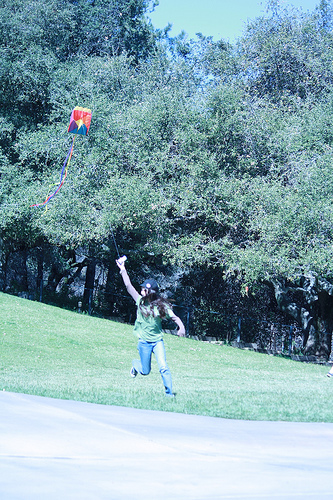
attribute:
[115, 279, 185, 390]
person — running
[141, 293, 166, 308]
hair — blowing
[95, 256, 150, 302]
arm — lifted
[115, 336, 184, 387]
legs — blue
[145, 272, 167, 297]
hat — blue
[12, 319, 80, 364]
grass — green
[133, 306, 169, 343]
shirt — green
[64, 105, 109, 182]
piece — red, purple, orange, yellow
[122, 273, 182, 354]
girl — light skinned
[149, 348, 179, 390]
leg — bent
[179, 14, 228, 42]
sky — blue